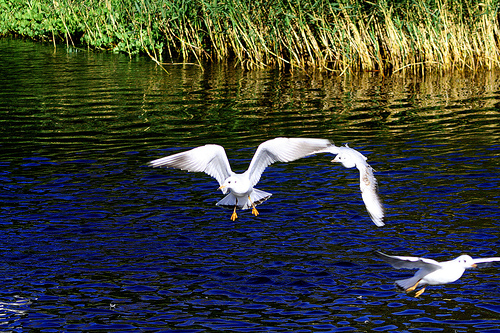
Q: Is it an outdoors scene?
A: Yes, it is outdoors.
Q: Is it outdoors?
A: Yes, it is outdoors.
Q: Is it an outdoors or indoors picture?
A: It is outdoors.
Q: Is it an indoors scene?
A: No, it is outdoors.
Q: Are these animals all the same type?
A: Yes, all the animals are birds.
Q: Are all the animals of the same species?
A: Yes, all the animals are birds.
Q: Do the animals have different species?
A: No, all the animals are birds.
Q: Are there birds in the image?
A: Yes, there is a bird.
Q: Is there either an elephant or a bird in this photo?
A: Yes, there is a bird.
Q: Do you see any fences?
A: No, there are no fences.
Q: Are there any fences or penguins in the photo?
A: No, there are no fences or penguins.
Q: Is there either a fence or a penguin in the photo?
A: No, there are no fences or penguins.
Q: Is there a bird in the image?
A: Yes, there is a bird.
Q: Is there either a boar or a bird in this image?
A: Yes, there is a bird.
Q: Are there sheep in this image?
A: No, there are no sheep.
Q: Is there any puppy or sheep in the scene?
A: No, there are no sheep or puppys.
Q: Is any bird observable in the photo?
A: Yes, there is a bird.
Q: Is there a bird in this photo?
A: Yes, there is a bird.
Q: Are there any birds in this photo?
A: Yes, there is a bird.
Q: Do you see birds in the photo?
A: Yes, there is a bird.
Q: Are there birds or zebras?
A: Yes, there is a bird.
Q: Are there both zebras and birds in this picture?
A: No, there is a bird but no zebras.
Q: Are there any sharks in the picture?
A: No, there are no sharks.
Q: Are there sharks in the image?
A: No, there are no sharks.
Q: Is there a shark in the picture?
A: No, there are no sharks.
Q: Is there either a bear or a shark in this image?
A: No, there are no sharks or bears.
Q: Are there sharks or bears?
A: No, there are no sharks or bears.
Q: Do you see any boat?
A: No, there are no boats.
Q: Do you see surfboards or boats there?
A: No, there are no boats or surfboards.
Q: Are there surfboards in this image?
A: No, there are no surfboards.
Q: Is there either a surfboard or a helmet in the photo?
A: No, there are no surfboards or helmets.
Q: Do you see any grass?
A: Yes, there is grass.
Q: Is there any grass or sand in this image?
A: Yes, there is grass.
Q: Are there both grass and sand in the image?
A: No, there is grass but no sand.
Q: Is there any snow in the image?
A: No, there is no snow.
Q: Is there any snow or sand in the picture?
A: No, there are no snow or sand.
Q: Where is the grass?
A: The grass is on the shore.